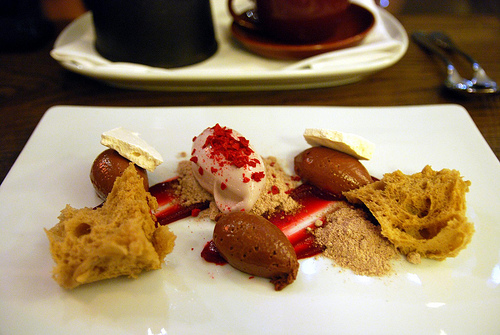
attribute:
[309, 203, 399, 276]
powder — brown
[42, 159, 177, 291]
bread — yellow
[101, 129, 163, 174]
butter — piece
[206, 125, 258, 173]
sprinkle — red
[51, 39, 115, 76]
napkin — white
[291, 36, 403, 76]
napkin — white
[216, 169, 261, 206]
cheese — white, piece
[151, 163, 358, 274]
sauce — red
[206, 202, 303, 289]
food — piece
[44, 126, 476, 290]
food — colored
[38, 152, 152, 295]
food — brown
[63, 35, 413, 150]
plates — white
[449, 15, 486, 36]
table — brown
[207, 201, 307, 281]
chocolate — brown, delicious, piece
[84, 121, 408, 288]
table mat — white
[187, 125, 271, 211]
dessert — small, cream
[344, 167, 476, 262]
bread — yellow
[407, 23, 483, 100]
silverware — silver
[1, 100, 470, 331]
plate — serving, white, dinner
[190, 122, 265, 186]
flakes — red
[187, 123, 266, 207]
food — white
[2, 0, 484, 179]
table — brown